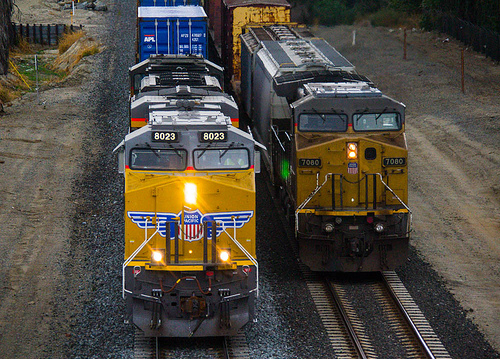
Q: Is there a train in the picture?
A: Yes, there is a train.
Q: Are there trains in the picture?
A: Yes, there is a train.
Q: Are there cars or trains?
A: Yes, there is a train.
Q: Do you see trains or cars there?
A: Yes, there is a train.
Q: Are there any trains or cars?
A: Yes, there is a train.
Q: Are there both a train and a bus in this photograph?
A: No, there is a train but no buses.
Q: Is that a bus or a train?
A: That is a train.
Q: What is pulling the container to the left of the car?
A: The train is pulling the container.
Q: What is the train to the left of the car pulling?
A: The train is pulling the container.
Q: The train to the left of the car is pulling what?
A: The train is pulling the container.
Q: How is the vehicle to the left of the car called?
A: The vehicle is a train.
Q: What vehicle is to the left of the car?
A: The vehicle is a train.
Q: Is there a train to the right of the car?
A: No, the train is to the left of the car.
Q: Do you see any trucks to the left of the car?
A: No, there is a train to the left of the car.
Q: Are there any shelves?
A: No, there are no shelves.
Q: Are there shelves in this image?
A: No, there are no shelves.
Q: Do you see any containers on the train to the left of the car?
A: Yes, there is a container on the train.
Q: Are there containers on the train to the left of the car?
A: Yes, there is a container on the train.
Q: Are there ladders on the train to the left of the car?
A: No, there is a container on the train.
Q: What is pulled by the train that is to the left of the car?
A: The container is pulled by the train.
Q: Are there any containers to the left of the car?
A: Yes, there is a container to the left of the car.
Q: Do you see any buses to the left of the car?
A: No, there is a container to the left of the car.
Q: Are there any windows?
A: Yes, there is a window.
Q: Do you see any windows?
A: Yes, there is a window.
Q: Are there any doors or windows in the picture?
A: Yes, there is a window.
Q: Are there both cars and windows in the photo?
A: Yes, there are both a window and a car.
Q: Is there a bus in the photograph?
A: No, there are no buses.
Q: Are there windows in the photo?
A: Yes, there is a window.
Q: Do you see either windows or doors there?
A: Yes, there is a window.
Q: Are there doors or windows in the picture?
A: Yes, there is a window.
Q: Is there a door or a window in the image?
A: Yes, there is a window.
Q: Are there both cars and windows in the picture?
A: Yes, there are both a window and a car.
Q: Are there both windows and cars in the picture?
A: Yes, there are both a window and a car.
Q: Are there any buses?
A: No, there are no buses.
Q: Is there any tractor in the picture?
A: No, there are no tractors.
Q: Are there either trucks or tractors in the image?
A: No, there are no tractors or trucks.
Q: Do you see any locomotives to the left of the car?
A: Yes, there is a locomotive to the left of the car.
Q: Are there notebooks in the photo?
A: No, there are no notebooks.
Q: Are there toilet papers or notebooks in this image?
A: No, there are no notebooks or toilet papers.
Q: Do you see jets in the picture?
A: No, there are no jets.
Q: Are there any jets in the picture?
A: No, there are no jets.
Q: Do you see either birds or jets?
A: No, there are no jets or birds.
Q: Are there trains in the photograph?
A: Yes, there is a train.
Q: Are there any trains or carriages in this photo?
A: Yes, there is a train.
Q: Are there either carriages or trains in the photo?
A: Yes, there is a train.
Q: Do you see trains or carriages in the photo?
A: Yes, there is a train.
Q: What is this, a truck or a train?
A: This is a train.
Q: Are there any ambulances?
A: No, there are no ambulances.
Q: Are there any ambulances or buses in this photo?
A: No, there are no ambulances or buses.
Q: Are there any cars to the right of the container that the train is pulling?
A: Yes, there is a car to the right of the container.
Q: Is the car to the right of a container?
A: Yes, the car is to the right of a container.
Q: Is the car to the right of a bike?
A: No, the car is to the right of a container.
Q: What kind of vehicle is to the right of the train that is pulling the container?
A: The vehicle is a car.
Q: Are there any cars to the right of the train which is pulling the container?
A: Yes, there is a car to the right of the train.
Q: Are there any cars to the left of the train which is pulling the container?
A: No, the car is to the right of the train.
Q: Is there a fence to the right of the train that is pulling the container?
A: No, there is a car to the right of the train.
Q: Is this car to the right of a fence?
A: No, the car is to the right of the train.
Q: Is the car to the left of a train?
A: No, the car is to the right of a train.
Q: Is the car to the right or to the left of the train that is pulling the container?
A: The car is to the right of the train.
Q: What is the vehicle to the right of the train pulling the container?
A: The vehicle is a locomotive.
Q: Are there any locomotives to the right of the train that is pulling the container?
A: Yes, there is a locomotive to the right of the train.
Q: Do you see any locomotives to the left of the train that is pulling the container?
A: No, the locomotive is to the right of the train.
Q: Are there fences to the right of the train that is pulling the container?
A: No, there is a locomotive to the right of the train.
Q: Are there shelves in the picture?
A: No, there are no shelves.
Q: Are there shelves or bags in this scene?
A: No, there are no shelves or bags.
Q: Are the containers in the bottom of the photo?
A: No, the containers are in the top of the image.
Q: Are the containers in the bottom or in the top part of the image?
A: The containers are in the top of the image.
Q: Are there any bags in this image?
A: No, there are no bags.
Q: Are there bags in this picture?
A: No, there are no bags.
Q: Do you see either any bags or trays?
A: No, there are no bags or trays.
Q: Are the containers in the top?
A: Yes, the containers are in the top of the image.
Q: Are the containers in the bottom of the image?
A: No, the containers are in the top of the image.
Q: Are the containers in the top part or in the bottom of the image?
A: The containers are in the top of the image.